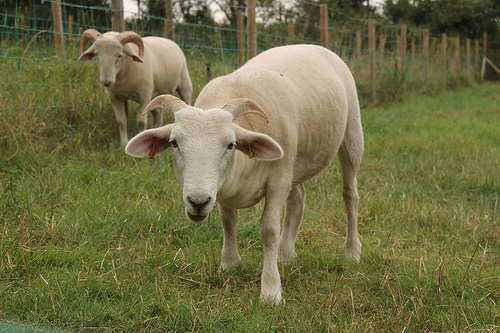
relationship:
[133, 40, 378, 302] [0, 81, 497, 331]
sheep in field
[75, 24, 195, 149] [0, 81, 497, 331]
sheep in field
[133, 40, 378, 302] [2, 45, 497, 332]
sheep in field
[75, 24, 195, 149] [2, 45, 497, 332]
sheep in field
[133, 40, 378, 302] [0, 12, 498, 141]
sheep behind a fence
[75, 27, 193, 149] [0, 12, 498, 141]
sheep behind a fence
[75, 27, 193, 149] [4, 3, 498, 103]
sheep behind a fence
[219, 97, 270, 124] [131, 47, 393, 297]
horn on sheep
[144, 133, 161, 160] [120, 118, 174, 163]
tag on ear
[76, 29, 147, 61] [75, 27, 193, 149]
horns on sheep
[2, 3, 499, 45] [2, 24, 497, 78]
trees near fence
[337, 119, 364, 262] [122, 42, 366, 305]
leg of sheep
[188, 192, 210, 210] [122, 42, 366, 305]
nose of sheep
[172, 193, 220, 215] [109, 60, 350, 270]
nostrils of sheep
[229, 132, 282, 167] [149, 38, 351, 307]
ear of sheep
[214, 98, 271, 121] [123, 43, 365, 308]
horn of sheep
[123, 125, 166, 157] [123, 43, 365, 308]
ear of sheep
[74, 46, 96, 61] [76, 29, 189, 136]
ear of goat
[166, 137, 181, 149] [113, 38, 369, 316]
eye of goat